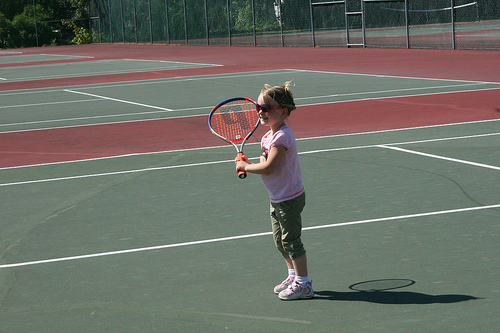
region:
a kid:
[231, 34, 364, 323]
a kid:
[203, 35, 328, 265]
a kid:
[248, 142, 369, 301]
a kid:
[223, 109, 323, 318]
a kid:
[245, 148, 317, 284]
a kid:
[277, 165, 351, 322]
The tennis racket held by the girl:
[202, 85, 262, 180]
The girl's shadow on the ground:
[301, 286, 481, 302]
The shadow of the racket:
[346, 265, 411, 290]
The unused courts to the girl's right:
[0, 11, 498, 135]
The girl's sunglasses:
[251, 101, 288, 113]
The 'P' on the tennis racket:
[217, 102, 254, 132]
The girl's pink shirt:
[251, 128, 308, 203]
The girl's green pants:
[265, 186, 305, 262]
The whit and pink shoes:
[274, 270, 314, 302]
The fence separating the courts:
[87, 1, 496, 54]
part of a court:
[188, 180, 230, 193]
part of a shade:
[361, 276, 394, 300]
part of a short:
[261, 192, 304, 262]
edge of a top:
[268, 175, 303, 199]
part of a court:
[162, 243, 221, 317]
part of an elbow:
[248, 142, 274, 185]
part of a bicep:
[258, 132, 289, 165]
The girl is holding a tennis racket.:
[200, 65, 337, 320]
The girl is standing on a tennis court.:
[23, 30, 448, 330]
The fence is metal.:
[88, 2, 498, 67]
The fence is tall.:
[86, 0, 498, 67]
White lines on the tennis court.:
[1, 41, 498, 329]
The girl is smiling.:
[193, 74, 326, 308]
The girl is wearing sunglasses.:
[198, 63, 343, 321]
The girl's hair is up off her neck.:
[201, 65, 340, 310]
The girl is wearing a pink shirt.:
[206, 67, 334, 304]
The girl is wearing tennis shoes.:
[188, 64, 330, 306]